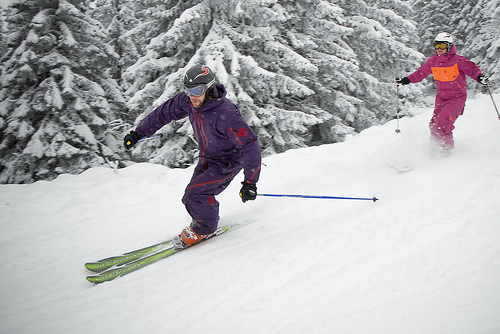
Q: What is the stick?
A: Blue.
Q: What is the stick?
A: Blue.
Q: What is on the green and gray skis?
A: The man.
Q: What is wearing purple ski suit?
A: The man.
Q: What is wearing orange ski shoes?
A: The man.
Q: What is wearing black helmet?
A: The man.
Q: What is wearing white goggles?
A: The man.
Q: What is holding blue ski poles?
A: The man.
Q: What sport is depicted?
A: Skiing.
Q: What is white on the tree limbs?
A: Snow.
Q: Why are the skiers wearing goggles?
A: Eye protection.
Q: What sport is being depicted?
A: Skiing.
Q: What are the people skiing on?
A: Snow.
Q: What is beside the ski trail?
A: Trees.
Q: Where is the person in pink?
A: Following person in purple.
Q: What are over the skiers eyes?
A: Goggles.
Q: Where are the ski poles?
A: Skiers hands.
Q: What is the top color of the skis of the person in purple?
A: Green and blue.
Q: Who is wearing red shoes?
A: Person in purple.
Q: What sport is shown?
A: Skiing.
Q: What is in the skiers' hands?
A: Poles.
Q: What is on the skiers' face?
A: Goggles.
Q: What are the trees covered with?
A: Snow.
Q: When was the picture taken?
A: Winter.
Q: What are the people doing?
A: Skiing.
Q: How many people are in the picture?
A: Two.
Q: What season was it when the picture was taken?
A: Winter.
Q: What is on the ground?
A: Snow.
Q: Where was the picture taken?
A: Mountain Slope.